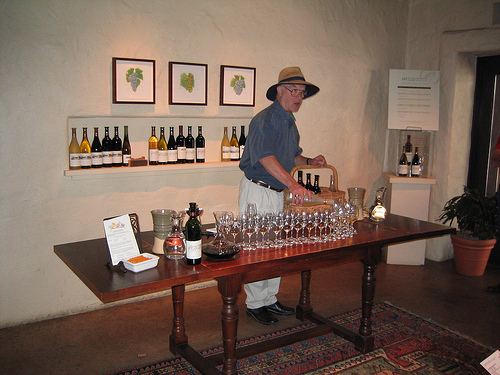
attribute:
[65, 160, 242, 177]
shelf — on wall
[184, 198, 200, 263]
wines — varieties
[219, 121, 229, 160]
wines — varieties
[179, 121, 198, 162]
wines — varieties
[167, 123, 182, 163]
wines — varieties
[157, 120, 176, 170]
wines — varieties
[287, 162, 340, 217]
basket — tan, wicker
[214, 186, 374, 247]
glasses — clear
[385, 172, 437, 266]
pedestal — white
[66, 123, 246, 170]
wine bottles — white, red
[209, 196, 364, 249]
glasses — similar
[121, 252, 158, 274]
container — white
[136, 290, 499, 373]
carpet — multi-colored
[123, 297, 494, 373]
rug — on floor, colorful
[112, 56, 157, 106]
wine decor — heritage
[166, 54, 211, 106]
wine decor — heritage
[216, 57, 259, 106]
wine decor — heritage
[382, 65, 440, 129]
poster — rectangular, white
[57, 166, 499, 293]
table — wooden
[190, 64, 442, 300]
man — on floor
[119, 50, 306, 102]
leaves — different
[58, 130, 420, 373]
tables — long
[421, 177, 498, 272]
plant — potted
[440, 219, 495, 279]
planter — orange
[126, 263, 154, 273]
container — little, white